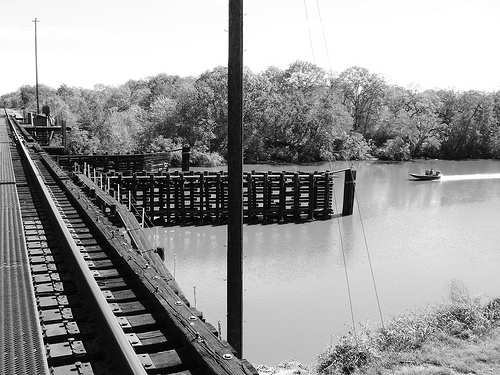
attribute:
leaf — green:
[163, 81, 179, 92]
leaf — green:
[208, 70, 246, 111]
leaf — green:
[133, 84, 152, 104]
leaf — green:
[267, 90, 286, 117]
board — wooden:
[137, 340, 199, 370]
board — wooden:
[114, 319, 188, 351]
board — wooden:
[101, 292, 171, 322]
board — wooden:
[81, 264, 136, 294]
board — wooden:
[36, 328, 100, 360]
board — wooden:
[25, 311, 98, 343]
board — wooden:
[22, 298, 100, 327]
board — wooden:
[30, 277, 68, 295]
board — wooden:
[28, 257, 57, 275]